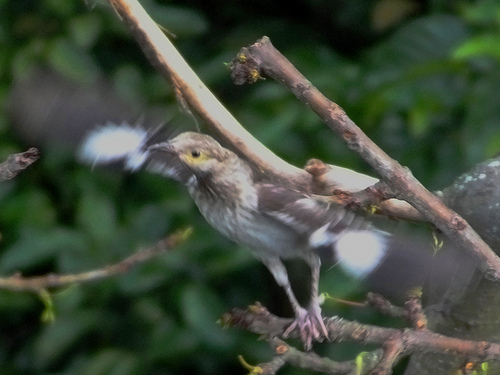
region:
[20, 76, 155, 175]
blurred wing in motion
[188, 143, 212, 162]
black eye on bird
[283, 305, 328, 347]
two feet on legs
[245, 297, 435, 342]
tree branch under feet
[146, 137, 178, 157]
beak on bird face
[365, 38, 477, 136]
green vegetation in the background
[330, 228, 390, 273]
white spot on bird wing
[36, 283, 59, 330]
blossom on tree branch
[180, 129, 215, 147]
top of bird head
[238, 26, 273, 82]
tip of tree branch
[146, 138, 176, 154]
this is beak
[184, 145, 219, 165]
this is a birds eye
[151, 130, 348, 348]
the bird is patched on atree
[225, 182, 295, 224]
these are feather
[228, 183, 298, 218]
the bird feather is white and grey in color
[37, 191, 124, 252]
these are green leaf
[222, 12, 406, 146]
this is a branch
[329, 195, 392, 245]
this is a bird tail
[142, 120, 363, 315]
this is a bird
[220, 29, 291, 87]
this is a broken branch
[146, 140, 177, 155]
Long gray beak of a bird.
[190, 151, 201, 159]
Round black eye of bird.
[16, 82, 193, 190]
Bird's gray and white wings in flight.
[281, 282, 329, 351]
Long skinny bird claws.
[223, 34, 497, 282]
Long thin branch of a tree.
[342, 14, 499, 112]
Rich green leaves of tree.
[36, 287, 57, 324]
New green shot of a branch.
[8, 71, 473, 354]
Gray and white bird in flight.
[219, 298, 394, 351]
Bird's claws releasing hold of branch.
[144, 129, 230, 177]
Small gray head of bird.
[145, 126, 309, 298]
the bird is brown in color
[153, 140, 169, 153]
the bird has sharp beak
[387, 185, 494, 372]
the branches are beside the bird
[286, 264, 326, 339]
the bird has thin legs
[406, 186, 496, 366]
the branches are dry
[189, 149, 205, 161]
the bird has black eyes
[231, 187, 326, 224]
the feathers are folded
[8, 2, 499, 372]
the photo is not clear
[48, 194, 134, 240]
the leaves are green in color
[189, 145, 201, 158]
the black eye of a bird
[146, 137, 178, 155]
the black beak of a bird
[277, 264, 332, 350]
the claws of a bird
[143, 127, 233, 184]
the head of a bird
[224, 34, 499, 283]
a large brown stick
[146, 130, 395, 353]
a bird on a branch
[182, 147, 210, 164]
yellow feathers around the bird's eye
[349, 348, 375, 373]
a green bud on the branch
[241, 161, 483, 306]
the wing of a bird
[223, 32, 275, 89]
the end of a branch